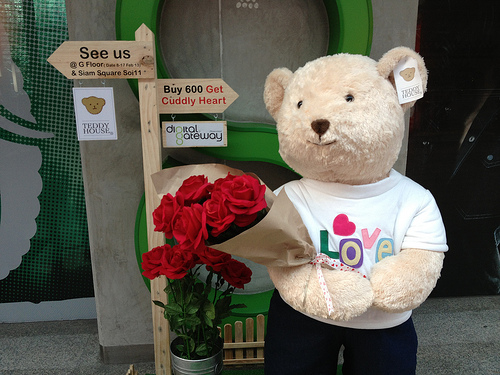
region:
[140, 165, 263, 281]
The flowers are roses.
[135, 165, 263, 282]
The flowers are red.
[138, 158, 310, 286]
The flowers are in paper.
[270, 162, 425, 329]
His shirt is white.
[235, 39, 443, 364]
The bear is tan.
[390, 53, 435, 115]
The tag is white.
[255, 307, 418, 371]
His pants are jeans.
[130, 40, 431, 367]
The bear is holding flowers.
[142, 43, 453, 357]
The bear is standing.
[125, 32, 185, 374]
The pole is wood.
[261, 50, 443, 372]
A brown teddy bear.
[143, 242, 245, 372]
Red roses in a pot.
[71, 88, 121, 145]
A small white sign.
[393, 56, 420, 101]
A white tag in the bear's ear.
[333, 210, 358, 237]
A pink heart on the t-shirt.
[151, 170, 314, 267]
Red roses wrapped in paper.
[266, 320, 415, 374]
Blue pants on the bear.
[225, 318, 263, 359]
Part of a small fence.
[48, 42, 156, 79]
A brown and black sign.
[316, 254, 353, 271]
Part of a red and white ribbon.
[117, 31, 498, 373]
bear is holding flowers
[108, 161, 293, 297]
the flowers are red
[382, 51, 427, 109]
tag in bear's are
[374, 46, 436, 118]
the tag is white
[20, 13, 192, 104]
the sign is brown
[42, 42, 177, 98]
black letters on sign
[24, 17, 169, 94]
sign is shape of left arrow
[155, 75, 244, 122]
red letters on sign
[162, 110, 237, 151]
the sign is white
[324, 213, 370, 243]
heart on the shirt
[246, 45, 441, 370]
A stuffed bear in a tshirt and pants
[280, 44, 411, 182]
The bear is tan in color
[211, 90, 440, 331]
The bear is carrying roses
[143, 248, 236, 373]
Fake roses in a metal container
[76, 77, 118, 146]
A white sign with a bear on it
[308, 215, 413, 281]
The shirt has LOVE on it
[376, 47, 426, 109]
The bear has a tag on his ear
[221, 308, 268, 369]
A small wood picket fence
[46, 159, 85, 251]
Green and white gingham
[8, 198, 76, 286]
White paint on a glass window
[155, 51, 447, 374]
a stuffed bear holding roses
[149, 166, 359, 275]
a bouquet of flowers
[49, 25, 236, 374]
a small wooden sign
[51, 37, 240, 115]
direction arrows on wooden post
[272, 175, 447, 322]
a white short sleeve shirt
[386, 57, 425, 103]
a tag on teddy bear ear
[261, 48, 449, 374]
teddy bear wearing clothes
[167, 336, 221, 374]
small metal pot with plants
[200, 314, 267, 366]
a mini picket fence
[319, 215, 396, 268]
Love decal on shirt